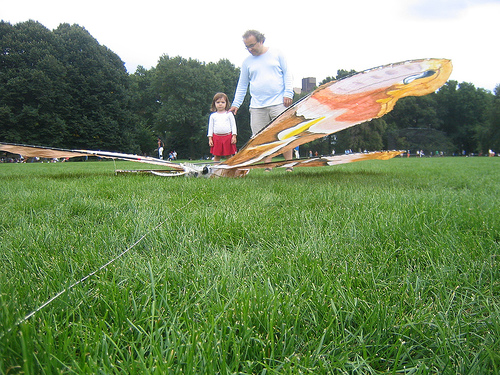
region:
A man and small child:
[176, 25, 296, 165]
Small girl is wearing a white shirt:
[200, 80, 240, 145]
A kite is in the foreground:
[0, 50, 480, 197]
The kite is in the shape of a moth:
[0, 50, 460, 180]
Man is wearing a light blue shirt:
[225, 50, 300, 106]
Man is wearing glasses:
[232, 30, 262, 52]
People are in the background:
[131, 135, 492, 160]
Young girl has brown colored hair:
[202, 85, 232, 110]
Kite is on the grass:
[3, 50, 469, 194]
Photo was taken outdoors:
[2, 5, 499, 369]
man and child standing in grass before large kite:
[5, 20, 462, 200]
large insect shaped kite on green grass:
[7, 50, 454, 184]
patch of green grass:
[250, 220, 458, 352]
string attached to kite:
[1, 165, 209, 344]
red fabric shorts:
[208, 134, 236, 159]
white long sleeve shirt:
[201, 110, 238, 136]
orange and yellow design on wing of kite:
[313, 58, 458, 130]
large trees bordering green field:
[2, 13, 498, 165]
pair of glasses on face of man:
[242, 37, 264, 52]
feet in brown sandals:
[262, 162, 299, 175]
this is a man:
[238, 25, 290, 114]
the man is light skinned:
[250, 45, 264, 50]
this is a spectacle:
[241, 40, 256, 50]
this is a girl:
[203, 88, 235, 150]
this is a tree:
[64, 29, 123, 116]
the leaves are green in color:
[84, 51, 109, 96]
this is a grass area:
[288, 174, 438, 362]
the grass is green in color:
[315, 261, 457, 349]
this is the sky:
[338, 18, 464, 59]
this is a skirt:
[216, 138, 230, 147]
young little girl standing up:
[207, 92, 235, 161]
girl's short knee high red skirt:
[210, 133, 234, 158]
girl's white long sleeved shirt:
[208, 111, 234, 135]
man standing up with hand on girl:
[231, 31, 299, 168]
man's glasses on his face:
[244, 42, 264, 49]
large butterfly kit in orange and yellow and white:
[0, 59, 442, 175]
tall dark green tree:
[2, 20, 151, 160]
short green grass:
[0, 155, 497, 374]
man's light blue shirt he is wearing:
[233, 53, 291, 108]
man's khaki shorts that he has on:
[249, 103, 284, 133]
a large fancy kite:
[12, 62, 482, 237]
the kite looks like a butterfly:
[1, 60, 498, 225]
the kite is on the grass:
[1, 55, 456, 185]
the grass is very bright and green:
[0, 165, 495, 371]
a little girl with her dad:
[196, 13, 309, 160]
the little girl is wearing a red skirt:
[206, 86, 247, 158]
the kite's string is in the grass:
[0, 170, 237, 316]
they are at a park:
[12, 0, 492, 370]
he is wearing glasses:
[238, 21, 271, 71]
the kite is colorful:
[2, 39, 481, 239]